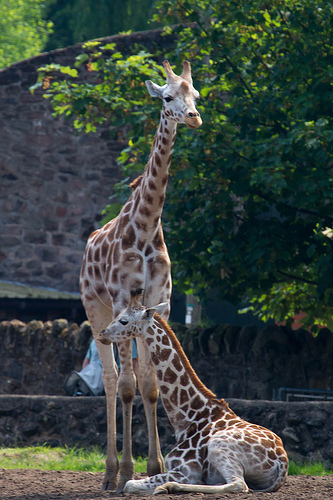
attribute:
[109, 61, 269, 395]
giraffe — standing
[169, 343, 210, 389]
mane — brown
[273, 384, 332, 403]
railing — green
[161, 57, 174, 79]
horn — gray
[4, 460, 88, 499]
dirt — brown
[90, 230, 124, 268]
spots — spotted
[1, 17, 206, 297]
wall — rock, behind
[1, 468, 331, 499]
ground — brown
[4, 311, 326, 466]
wall — brown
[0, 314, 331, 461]
fence — stone, behind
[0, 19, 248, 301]
wall — brown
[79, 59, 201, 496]
giraffe — tired, standing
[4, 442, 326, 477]
grass — brown, green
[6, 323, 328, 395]
wall — green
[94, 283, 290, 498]
giraffe — brown, patterned, white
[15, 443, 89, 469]
grass — brown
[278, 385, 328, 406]
metal pipes — gray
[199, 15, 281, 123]
leaves — brown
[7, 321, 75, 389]
wall — brown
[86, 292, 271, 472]
giraffe — spotted